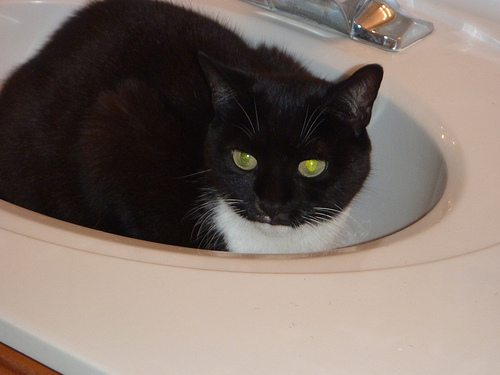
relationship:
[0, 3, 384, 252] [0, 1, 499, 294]
cat sitting in sink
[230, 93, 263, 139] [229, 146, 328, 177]
whiskers above eyes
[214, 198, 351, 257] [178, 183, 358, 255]
patch on chest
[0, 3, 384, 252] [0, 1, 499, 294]
cat in sink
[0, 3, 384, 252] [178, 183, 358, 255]
cat has chest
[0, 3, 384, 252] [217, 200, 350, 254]
cat has white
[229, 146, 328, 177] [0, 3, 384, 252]
eyes of cat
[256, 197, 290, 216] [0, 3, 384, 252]
nose of cat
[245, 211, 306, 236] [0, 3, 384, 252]
mouth of cat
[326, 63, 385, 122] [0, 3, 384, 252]
ear of cat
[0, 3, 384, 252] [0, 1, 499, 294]
cat laying in sink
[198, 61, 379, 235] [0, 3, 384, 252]
head of cat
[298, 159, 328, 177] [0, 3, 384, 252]
eye of cat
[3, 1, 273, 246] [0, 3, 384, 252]
fur of cat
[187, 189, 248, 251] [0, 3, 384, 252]
whiskers of cat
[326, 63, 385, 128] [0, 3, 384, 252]
ear on cat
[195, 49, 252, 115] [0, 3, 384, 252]
ears on cat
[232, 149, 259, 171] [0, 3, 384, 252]
eyes on cat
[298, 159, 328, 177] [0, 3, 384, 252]
eye on cat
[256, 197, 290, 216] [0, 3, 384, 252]
nose on cat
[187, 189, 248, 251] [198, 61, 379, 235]
whiskers on head